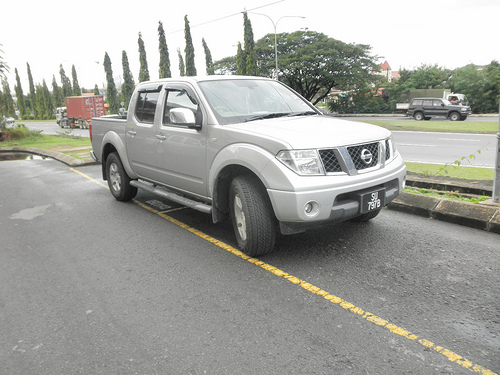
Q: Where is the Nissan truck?
A: Parked.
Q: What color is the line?
A: Yellow.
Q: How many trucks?
A: Three.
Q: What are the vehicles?
A: Trucks.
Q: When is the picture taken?
A: Daytime.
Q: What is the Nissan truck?
A: A pickup.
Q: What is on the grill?
A: An emblem.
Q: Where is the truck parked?
A: In the yellow line.